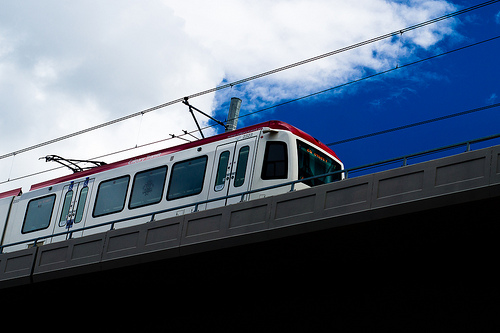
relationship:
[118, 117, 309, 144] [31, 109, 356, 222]
red roof on train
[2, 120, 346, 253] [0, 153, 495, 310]
train on bridge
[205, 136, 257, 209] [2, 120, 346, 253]
doors of train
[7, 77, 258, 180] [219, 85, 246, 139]
cable with pole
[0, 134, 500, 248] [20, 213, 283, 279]
metal railing on wall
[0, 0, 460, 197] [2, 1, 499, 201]
cloud in sky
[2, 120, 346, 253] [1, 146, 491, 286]
train on platform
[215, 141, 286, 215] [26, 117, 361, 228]
doors on train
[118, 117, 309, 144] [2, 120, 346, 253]
red roof on train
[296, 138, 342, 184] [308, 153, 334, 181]
glass with a wiper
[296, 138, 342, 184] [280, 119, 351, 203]
glass on front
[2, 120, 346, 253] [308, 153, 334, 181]
train has a wiper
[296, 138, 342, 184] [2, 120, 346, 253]
glass on train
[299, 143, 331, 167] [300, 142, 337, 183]
display board on window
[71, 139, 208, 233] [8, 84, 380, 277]
panes on train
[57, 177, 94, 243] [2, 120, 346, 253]
doors on train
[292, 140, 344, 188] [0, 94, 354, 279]
window on train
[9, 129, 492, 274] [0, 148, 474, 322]
metal railing on bridge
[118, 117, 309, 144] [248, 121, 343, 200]
red roof on train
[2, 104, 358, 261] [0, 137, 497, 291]
train running in flyover railroad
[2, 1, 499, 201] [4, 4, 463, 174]
sky with cloud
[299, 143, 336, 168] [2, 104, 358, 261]
display board of train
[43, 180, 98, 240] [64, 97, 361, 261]
door of train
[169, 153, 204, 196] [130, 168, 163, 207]
window on window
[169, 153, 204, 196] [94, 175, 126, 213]
window on window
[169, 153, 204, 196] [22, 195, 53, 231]
window on window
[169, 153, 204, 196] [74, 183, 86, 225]
window on window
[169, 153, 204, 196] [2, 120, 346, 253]
window on train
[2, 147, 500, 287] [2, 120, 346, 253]
stone next to train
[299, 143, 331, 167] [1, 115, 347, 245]
display board on bus